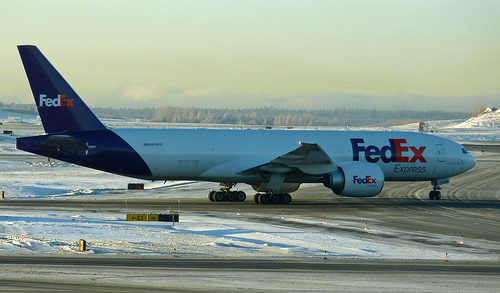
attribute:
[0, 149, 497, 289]
runway — snowy 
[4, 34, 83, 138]
fin — large blue tail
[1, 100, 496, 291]
landscape — snowy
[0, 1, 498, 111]
sky — blue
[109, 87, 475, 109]
clouds — white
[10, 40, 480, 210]
airplane — fedex 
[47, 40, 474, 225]
airplane — Fed Ex